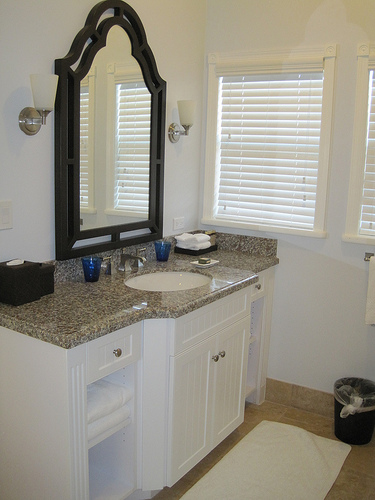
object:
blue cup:
[81, 257, 103, 282]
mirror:
[79, 26, 154, 231]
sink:
[123, 269, 212, 292]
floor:
[167, 380, 373, 497]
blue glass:
[153, 239, 172, 261]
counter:
[1, 229, 279, 348]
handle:
[113, 347, 123, 357]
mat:
[175, 418, 349, 500]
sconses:
[18, 105, 50, 136]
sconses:
[167, 122, 195, 143]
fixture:
[29, 71, 57, 112]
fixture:
[177, 95, 196, 125]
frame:
[51, 1, 167, 261]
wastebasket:
[332, 374, 375, 445]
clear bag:
[332, 376, 375, 420]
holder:
[0, 258, 54, 306]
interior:
[0, 0, 368, 236]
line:
[248, 406, 264, 412]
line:
[221, 434, 242, 454]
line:
[346, 466, 373, 479]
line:
[283, 414, 332, 431]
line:
[276, 406, 292, 421]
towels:
[173, 232, 211, 250]